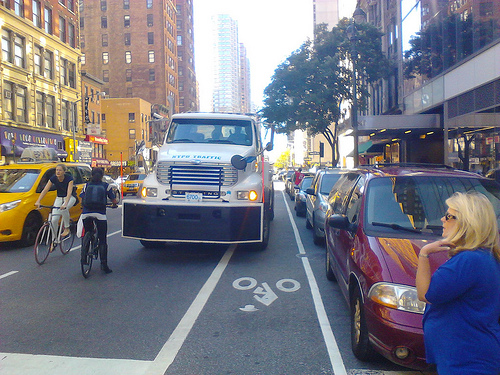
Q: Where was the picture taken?
A: It was taken at the street.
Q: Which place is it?
A: It is a street.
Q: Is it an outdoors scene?
A: Yes, it is outdoors.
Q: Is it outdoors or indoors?
A: It is outdoors.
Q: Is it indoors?
A: No, it is outdoors.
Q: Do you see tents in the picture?
A: No, there are no tents.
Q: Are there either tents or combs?
A: No, there are no tents or combs.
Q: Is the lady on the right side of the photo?
A: Yes, the lady is on the right of the image.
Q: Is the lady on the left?
A: No, the lady is on the right of the image.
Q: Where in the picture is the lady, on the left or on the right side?
A: The lady is on the right of the image.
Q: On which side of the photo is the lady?
A: The lady is on the right of the image.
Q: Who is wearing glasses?
A: The lady is wearing glasses.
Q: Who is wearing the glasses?
A: The lady is wearing glasses.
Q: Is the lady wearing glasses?
A: Yes, the lady is wearing glasses.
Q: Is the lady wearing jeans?
A: No, the lady is wearing glasses.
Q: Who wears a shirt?
A: The lady wears a shirt.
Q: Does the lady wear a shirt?
A: Yes, the lady wears a shirt.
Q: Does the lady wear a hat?
A: No, the lady wears a shirt.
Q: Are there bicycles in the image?
A: Yes, there is a bicycle.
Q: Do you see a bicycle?
A: Yes, there is a bicycle.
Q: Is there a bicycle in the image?
A: Yes, there is a bicycle.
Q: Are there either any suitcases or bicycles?
A: Yes, there is a bicycle.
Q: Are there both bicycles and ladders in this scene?
A: No, there is a bicycle but no ladders.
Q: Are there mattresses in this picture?
A: No, there are no mattresses.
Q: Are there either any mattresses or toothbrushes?
A: No, there are no mattresses or toothbrushes.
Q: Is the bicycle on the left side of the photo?
A: Yes, the bicycle is on the left of the image.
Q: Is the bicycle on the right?
A: No, the bicycle is on the left of the image.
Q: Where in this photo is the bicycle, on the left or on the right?
A: The bicycle is on the left of the image.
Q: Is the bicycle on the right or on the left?
A: The bicycle is on the left of the image.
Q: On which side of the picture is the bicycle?
A: The bicycle is on the left of the image.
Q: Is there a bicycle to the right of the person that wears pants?
A: Yes, there is a bicycle to the right of the person.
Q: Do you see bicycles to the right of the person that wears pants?
A: Yes, there is a bicycle to the right of the person.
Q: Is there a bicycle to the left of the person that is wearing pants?
A: No, the bicycle is to the right of the person.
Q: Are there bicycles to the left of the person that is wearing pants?
A: No, the bicycle is to the right of the person.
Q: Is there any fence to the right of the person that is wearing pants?
A: No, there is a bicycle to the right of the person.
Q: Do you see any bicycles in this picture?
A: Yes, there is a bicycle.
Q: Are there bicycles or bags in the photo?
A: Yes, there is a bicycle.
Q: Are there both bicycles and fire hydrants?
A: No, there is a bicycle but no fire hydrants.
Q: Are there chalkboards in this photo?
A: No, there are no chalkboards.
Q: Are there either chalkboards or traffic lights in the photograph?
A: No, there are no chalkboards or traffic lights.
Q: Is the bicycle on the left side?
A: Yes, the bicycle is on the left of the image.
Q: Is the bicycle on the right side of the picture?
A: No, the bicycle is on the left of the image.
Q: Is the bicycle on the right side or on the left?
A: The bicycle is on the left of the image.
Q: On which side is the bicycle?
A: The bicycle is on the left of the image.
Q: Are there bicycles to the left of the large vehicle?
A: Yes, there is a bicycle to the left of the truck.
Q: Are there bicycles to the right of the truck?
A: No, the bicycle is to the left of the truck.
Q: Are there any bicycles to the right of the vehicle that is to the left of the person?
A: No, the bicycle is to the left of the truck.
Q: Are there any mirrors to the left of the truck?
A: No, there is a bicycle to the left of the truck.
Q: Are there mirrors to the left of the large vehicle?
A: No, there is a bicycle to the left of the truck.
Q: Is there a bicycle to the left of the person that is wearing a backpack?
A: Yes, there is a bicycle to the left of the person.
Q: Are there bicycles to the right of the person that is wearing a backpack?
A: No, the bicycle is to the left of the person.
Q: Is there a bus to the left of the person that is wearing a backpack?
A: No, there is a bicycle to the left of the person.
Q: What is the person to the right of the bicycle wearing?
A: The person is wearing a backpack.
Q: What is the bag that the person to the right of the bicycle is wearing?
A: The bag is a backpack.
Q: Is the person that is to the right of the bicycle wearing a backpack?
A: Yes, the person is wearing a backpack.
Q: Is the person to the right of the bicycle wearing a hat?
A: No, the person is wearing a backpack.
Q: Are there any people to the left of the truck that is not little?
A: Yes, there is a person to the left of the truck.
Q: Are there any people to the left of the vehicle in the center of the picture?
A: Yes, there is a person to the left of the truck.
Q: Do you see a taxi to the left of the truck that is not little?
A: No, there is a person to the left of the truck.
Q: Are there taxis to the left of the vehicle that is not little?
A: No, there is a person to the left of the truck.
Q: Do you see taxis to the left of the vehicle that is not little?
A: No, there is a person to the left of the truck.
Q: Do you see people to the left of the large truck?
A: Yes, there is a person to the left of the truck.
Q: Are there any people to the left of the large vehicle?
A: Yes, there is a person to the left of the truck.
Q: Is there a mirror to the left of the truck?
A: No, there is a person to the left of the truck.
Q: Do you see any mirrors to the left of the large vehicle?
A: No, there is a person to the left of the truck.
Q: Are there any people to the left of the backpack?
A: Yes, there is a person to the left of the backpack.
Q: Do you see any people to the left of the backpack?
A: Yes, there is a person to the left of the backpack.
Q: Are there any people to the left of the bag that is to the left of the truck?
A: Yes, there is a person to the left of the backpack.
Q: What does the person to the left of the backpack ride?
A: The person rides the bicycle.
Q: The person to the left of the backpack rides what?
A: The person rides the bicycle.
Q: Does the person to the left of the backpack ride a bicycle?
A: Yes, the person rides a bicycle.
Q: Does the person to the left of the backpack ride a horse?
A: No, the person rides a bicycle.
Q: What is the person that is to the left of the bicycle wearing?
A: The person is wearing pants.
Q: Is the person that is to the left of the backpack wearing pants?
A: Yes, the person is wearing pants.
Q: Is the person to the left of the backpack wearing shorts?
A: No, the person is wearing pants.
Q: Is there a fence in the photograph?
A: No, there are no fences.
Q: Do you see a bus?
A: No, there are no buses.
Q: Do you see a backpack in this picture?
A: Yes, there is a backpack.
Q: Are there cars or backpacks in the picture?
A: Yes, there is a backpack.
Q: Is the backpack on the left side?
A: Yes, the backpack is on the left of the image.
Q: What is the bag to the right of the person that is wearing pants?
A: The bag is a backpack.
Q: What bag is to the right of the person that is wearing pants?
A: The bag is a backpack.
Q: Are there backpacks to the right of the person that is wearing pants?
A: Yes, there is a backpack to the right of the person.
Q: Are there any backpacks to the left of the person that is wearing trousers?
A: No, the backpack is to the right of the person.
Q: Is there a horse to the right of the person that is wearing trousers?
A: No, there is a backpack to the right of the person.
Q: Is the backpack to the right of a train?
A: No, the backpack is to the right of the person.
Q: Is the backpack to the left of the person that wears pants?
A: No, the backpack is to the right of the person.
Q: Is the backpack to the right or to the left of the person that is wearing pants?
A: The backpack is to the right of the person.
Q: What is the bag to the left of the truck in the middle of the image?
A: The bag is a backpack.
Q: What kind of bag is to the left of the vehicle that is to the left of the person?
A: The bag is a backpack.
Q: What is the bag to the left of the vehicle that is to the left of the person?
A: The bag is a backpack.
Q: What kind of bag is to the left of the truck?
A: The bag is a backpack.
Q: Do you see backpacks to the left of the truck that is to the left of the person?
A: Yes, there is a backpack to the left of the truck.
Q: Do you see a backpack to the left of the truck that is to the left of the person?
A: Yes, there is a backpack to the left of the truck.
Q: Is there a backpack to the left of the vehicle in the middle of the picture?
A: Yes, there is a backpack to the left of the truck.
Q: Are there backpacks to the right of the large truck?
A: No, the backpack is to the left of the truck.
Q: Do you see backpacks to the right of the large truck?
A: No, the backpack is to the left of the truck.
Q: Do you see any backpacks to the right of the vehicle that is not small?
A: No, the backpack is to the left of the truck.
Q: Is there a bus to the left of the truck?
A: No, there is a backpack to the left of the truck.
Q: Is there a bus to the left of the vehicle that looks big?
A: No, there is a backpack to the left of the truck.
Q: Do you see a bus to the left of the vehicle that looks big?
A: No, there is a backpack to the left of the truck.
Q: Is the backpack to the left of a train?
A: No, the backpack is to the left of a truck.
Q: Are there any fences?
A: No, there are no fences.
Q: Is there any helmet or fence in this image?
A: No, there are no fences or helmets.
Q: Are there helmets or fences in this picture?
A: No, there are no fences or helmets.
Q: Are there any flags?
A: No, there are no flags.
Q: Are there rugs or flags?
A: No, there are no flags or rugs.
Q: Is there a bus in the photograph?
A: No, there are no buses.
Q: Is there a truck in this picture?
A: Yes, there is a truck.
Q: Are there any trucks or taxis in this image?
A: Yes, there is a truck.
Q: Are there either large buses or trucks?
A: Yes, there is a large truck.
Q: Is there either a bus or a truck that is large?
A: Yes, the truck is large.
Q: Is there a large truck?
A: Yes, there is a large truck.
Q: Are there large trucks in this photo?
A: Yes, there is a large truck.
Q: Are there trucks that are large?
A: Yes, there is a truck that is large.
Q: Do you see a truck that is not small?
A: Yes, there is a large truck.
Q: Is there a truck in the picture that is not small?
A: Yes, there is a large truck.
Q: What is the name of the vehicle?
A: The vehicle is a truck.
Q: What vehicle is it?
A: The vehicle is a truck.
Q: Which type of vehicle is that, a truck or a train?
A: This is a truck.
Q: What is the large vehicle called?
A: The vehicle is a truck.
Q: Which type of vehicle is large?
A: The vehicle is a truck.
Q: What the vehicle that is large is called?
A: The vehicle is a truck.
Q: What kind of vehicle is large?
A: The vehicle is a truck.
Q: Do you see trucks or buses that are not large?
A: No, there is a truck but it is large.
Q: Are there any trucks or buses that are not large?
A: No, there is a truck but it is large.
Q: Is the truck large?
A: Yes, the truck is large.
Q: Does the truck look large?
A: Yes, the truck is large.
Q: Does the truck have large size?
A: Yes, the truck is large.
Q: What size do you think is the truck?
A: The truck is large.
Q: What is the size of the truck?
A: The truck is large.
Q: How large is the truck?
A: The truck is large.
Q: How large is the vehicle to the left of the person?
A: The truck is large.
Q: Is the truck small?
A: No, the truck is large.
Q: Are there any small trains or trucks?
A: No, there is a truck but it is large.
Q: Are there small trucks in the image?
A: No, there is a truck but it is large.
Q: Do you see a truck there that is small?
A: No, there is a truck but it is large.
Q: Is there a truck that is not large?
A: No, there is a truck but it is large.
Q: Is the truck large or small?
A: The truck is large.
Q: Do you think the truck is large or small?
A: The truck is large.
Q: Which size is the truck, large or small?
A: The truck is large.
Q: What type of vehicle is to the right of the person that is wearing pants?
A: The vehicle is a truck.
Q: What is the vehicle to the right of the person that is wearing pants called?
A: The vehicle is a truck.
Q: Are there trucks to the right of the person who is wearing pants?
A: Yes, there is a truck to the right of the person.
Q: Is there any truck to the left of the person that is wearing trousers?
A: No, the truck is to the right of the person.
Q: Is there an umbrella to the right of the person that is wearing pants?
A: No, there is a truck to the right of the person.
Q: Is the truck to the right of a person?
A: Yes, the truck is to the right of a person.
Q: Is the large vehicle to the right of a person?
A: Yes, the truck is to the right of a person.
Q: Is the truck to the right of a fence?
A: No, the truck is to the right of a person.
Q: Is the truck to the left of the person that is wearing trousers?
A: No, the truck is to the right of the person.